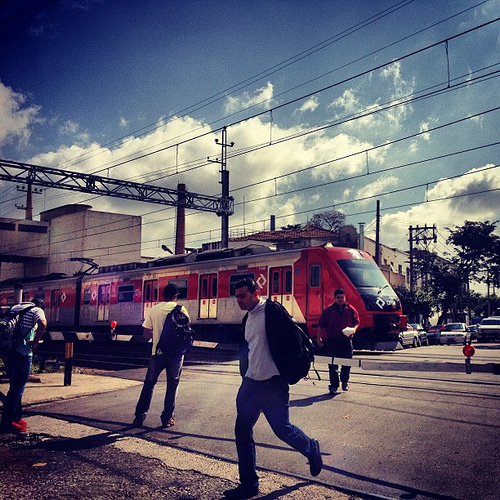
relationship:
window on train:
[92, 280, 133, 301] [1, 230, 410, 352]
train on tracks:
[1, 246, 407, 355] [383, 337, 496, 425]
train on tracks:
[1, 230, 410, 352] [76, 357, 147, 371]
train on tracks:
[1, 246, 407, 355] [366, 310, 498, 404]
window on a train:
[336, 256, 396, 293] [1, 230, 410, 352]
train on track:
[1, 246, 407, 355] [365, 336, 479, 387]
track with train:
[50, 270, 468, 431] [68, 188, 472, 365]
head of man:
[333, 289, 347, 307] [222, 279, 323, 496]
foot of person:
[221, 480, 259, 498] [154, 283, 352, 495]